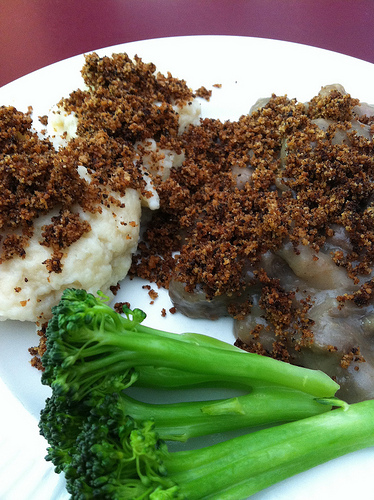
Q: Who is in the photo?
A: No one.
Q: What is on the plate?
A: Food.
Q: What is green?
A: Broccoli.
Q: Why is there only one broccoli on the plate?
A: The person to eat is one.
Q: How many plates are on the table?
A: 1.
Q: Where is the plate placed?
A: On top of a table.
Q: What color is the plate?
A: White.